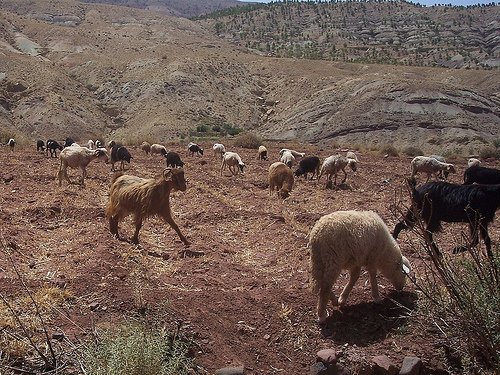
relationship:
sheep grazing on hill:
[299, 201, 418, 326] [3, 136, 496, 371]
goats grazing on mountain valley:
[0, 134, 499, 324] [1, 5, 493, 373]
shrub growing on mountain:
[83, 307, 188, 372] [213, 2, 498, 72]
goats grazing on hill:
[0, 134, 499, 324] [3, 136, 496, 371]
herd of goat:
[3, 132, 490, 313] [94, 157, 190, 249]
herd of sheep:
[3, 132, 490, 313] [299, 201, 418, 326]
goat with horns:
[94, 157, 190, 249] [108, 162, 194, 247]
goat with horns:
[94, 157, 190, 249] [169, 163, 182, 168]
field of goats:
[7, 90, 467, 324] [83, 141, 424, 245]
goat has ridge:
[390, 177, 496, 257] [425, 178, 480, 190]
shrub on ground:
[83, 307, 188, 372] [4, 139, 496, 370]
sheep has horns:
[106, 146, 196, 249] [160, 163, 182, 180]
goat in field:
[390, 177, 496, 257] [5, 1, 498, 369]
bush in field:
[73, 292, 210, 372] [83, 73, 451, 330]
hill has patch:
[112, 57, 260, 137] [191, 122, 246, 136]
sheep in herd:
[299, 201, 418, 326] [3, 132, 490, 313]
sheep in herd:
[106, 146, 196, 249] [3, 132, 490, 313]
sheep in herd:
[267, 162, 295, 197] [3, 132, 490, 313]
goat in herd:
[390, 177, 496, 257] [3, 132, 490, 313]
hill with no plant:
[2, 10, 496, 374] [126, 325, 182, 362]